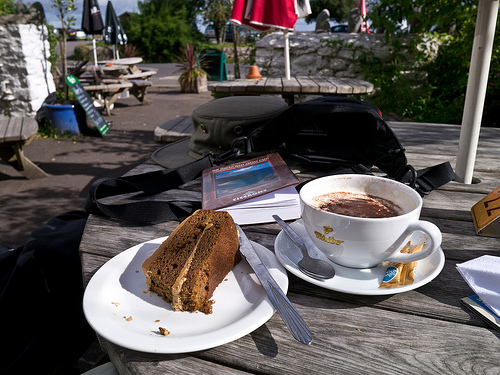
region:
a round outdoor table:
[71, 88, 493, 374]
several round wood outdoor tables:
[69, 34, 499, 366]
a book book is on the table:
[178, 145, 301, 225]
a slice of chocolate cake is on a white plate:
[79, 218, 305, 355]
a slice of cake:
[143, 201, 246, 319]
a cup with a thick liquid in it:
[275, 173, 447, 296]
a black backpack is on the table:
[99, 90, 454, 233]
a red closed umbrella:
[223, 0, 311, 77]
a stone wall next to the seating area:
[249, 25, 499, 125]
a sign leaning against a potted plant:
[60, 65, 114, 139]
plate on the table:
[67, 209, 285, 339]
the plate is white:
[72, 214, 294, 357]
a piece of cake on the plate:
[130, 196, 256, 310]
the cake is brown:
[124, 191, 266, 315]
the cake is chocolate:
[108, 177, 272, 320]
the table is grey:
[154, 285, 354, 368]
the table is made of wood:
[245, 295, 487, 372]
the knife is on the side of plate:
[210, 212, 322, 361]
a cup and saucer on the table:
[275, 149, 452, 337]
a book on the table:
[194, 130, 320, 223]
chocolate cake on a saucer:
[135, 183, 276, 314]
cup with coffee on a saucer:
[289, 163, 452, 301]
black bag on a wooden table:
[155, 49, 432, 162]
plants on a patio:
[176, 42, 213, 92]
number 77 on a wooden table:
[460, 183, 497, 238]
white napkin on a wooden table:
[457, 244, 498, 333]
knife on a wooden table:
[235, 231, 305, 356]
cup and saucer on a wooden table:
[277, 171, 455, 308]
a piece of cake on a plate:
[95, 208, 272, 337]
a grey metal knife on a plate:
[228, 210, 275, 358]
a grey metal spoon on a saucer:
[276, 207, 332, 291]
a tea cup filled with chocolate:
[303, 167, 413, 269]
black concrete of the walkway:
[51, 130, 106, 178]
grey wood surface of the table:
[343, 315, 468, 373]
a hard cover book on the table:
[199, 153, 296, 219]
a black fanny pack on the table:
[226, 98, 449, 188]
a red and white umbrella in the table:
[221, 0, 319, 45]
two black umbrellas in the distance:
[74, 2, 133, 57]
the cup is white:
[292, 172, 444, 269]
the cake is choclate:
[151, 202, 236, 316]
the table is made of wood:
[341, 313, 461, 373]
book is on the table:
[198, 155, 293, 219]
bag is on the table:
[191, 94, 411, 162]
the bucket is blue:
[41, 98, 89, 138]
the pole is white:
[454, 35, 499, 162]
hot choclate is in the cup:
[307, 173, 439, 283]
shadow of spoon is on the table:
[247, 326, 282, 365]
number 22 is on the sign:
[460, 180, 497, 226]